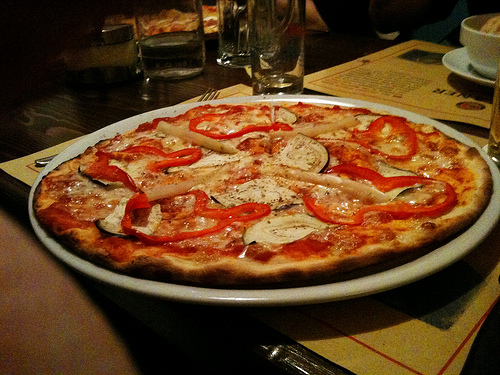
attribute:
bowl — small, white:
[453, 21, 497, 88]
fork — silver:
[191, 86, 226, 103]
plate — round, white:
[56, 49, 472, 342]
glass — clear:
[235, 0, 337, 107]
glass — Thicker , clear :
[133, 4, 203, 85]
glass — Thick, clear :
[244, 5, 307, 97]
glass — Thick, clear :
[213, 1, 258, 76]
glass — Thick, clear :
[66, 13, 146, 82]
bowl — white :
[454, 10, 499, 70]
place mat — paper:
[0, 79, 498, 372]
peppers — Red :
[94, 110, 456, 242]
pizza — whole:
[70, 117, 448, 289]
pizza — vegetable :
[50, 94, 492, 256]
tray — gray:
[31, 89, 484, 311]